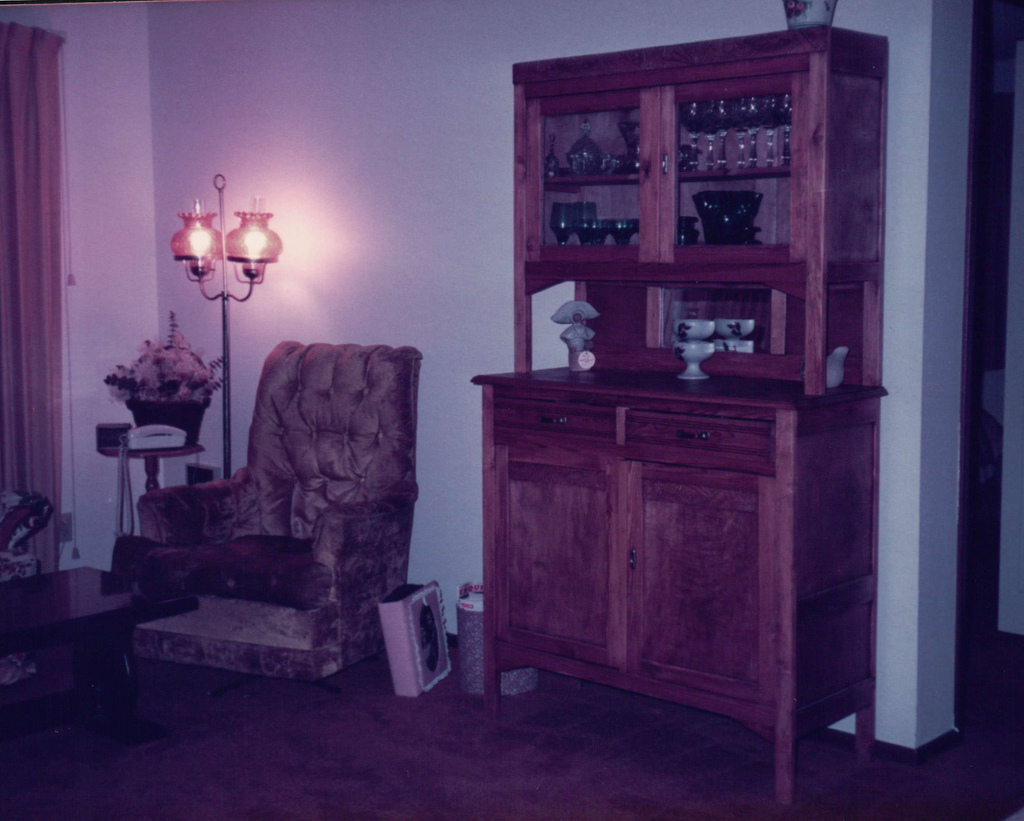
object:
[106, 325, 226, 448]
flower arrangement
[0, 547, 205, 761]
coffee table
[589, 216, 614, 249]
glass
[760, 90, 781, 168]
glass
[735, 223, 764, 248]
glass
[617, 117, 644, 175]
glass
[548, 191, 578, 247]
glass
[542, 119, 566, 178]
glass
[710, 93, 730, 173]
glass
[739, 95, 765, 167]
glass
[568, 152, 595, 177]
glass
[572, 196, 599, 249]
glass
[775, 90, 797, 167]
glass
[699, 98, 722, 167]
glass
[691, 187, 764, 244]
glass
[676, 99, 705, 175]
glass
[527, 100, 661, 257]
cabinet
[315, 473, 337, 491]
button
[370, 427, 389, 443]
button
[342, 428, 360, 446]
button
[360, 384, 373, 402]
button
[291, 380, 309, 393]
button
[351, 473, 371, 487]
button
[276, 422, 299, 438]
button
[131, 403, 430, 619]
recliner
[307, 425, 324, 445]
button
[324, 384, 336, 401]
button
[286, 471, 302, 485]
button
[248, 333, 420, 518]
recliner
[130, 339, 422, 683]
chair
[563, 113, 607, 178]
glass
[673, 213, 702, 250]
glass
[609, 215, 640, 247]
glass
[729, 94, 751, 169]
glass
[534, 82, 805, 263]
hutch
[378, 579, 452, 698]
album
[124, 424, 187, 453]
phone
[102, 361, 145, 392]
flowers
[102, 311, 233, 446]
basket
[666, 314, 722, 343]
dishware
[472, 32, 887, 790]
cupboard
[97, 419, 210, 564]
table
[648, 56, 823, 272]
cabinet